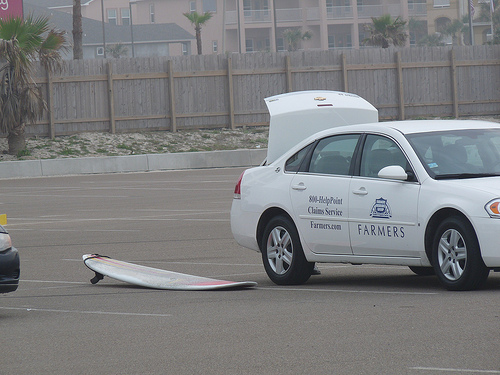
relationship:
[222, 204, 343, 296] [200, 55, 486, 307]
wheel on car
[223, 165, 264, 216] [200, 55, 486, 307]
blinker on car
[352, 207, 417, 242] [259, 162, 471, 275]
name on side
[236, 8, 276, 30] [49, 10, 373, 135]
window of building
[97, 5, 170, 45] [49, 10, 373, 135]
roof of building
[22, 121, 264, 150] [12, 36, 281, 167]
stones in front of fence